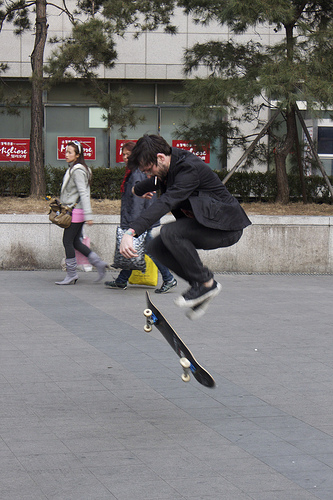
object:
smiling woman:
[39, 122, 104, 287]